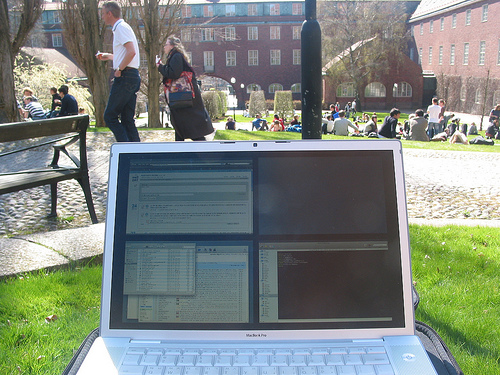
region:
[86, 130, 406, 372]
a laptop computer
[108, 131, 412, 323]
a laptop screen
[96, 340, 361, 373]
the keyboard on a laptop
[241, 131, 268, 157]
the camera on a laptop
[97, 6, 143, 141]
a man with a white shirt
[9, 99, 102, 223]
part of a bench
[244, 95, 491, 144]
many people sitting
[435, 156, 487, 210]
a gray pathway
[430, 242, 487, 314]
green grass near the walkway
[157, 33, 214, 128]
a woman with a backpack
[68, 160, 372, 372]
laptop computer is on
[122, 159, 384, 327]
four windows open on laptop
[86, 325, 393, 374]
white keyboard on Macbook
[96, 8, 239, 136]
man and woman are walking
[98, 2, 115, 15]
man has grey hair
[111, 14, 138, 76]
man has white shirt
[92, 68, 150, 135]
man has blue pants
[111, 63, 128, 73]
man wears watch on left hand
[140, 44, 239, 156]
woman wears black coat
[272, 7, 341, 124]
black pole in front of laptop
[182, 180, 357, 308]
screen on a laptop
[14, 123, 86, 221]
bench on the walkway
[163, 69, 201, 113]
woman is carrying a bag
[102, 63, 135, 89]
man's hand is in his pocket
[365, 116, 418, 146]
people sitting on the grass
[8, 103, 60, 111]
people sitting next to tree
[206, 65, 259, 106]
arch walkway on the building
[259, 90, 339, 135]
pole behind the laptop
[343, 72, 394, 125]
tree in front of building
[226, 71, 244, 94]
street light next to walkway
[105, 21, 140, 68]
A white shirt in the photo.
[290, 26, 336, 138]
A metal pole in the photo.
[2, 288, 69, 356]
Grass in the photo.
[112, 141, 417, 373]
A laptop in the photo.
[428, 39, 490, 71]
Windows in the photo.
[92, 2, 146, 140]
A man in the photo.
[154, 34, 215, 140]
A woman in the photo.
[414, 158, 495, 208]
A paved road in the photo.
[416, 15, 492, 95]
A building in the photo.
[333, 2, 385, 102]
A tree in the photo.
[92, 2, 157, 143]
this is a person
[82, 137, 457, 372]
this is a laptop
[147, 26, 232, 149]
this is a person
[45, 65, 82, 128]
this is a person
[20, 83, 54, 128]
this is a person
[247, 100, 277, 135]
this is a person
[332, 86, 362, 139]
this is a person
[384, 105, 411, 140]
this is a person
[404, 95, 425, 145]
this is a person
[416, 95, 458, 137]
this is a person